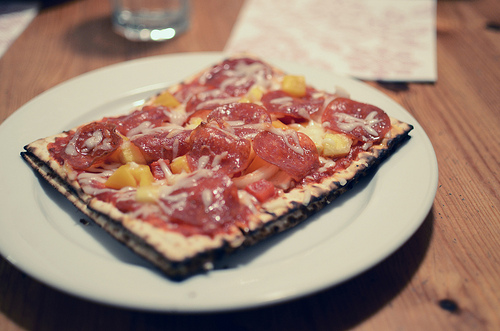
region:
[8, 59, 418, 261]
Flatbread pizza on a white plate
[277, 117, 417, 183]
Burnt edges of flatbread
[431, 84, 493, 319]
Wood table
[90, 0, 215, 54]
Drinking glass on the table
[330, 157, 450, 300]
White plate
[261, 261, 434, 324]
Shadow of the plate on a table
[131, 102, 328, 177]
Many pieces of pepperoni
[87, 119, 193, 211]
Tomato sauce, cheese, and pepperoni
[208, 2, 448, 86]
Paper menu sitting on the table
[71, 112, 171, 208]
Yellow and red pizza toppings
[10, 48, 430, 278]
This is flat bread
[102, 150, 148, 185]
this is yellow cheese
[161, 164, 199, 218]
this is white cheese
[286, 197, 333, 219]
this is burnt bread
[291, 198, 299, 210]
this is the color black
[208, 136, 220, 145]
this is the color red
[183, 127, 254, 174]
this is a pepperoni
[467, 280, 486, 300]
this is the color brown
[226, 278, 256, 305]
this is the color white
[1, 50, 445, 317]
this is a round plate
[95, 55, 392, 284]
pizza on a plate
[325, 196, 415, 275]
white plate above table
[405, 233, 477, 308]
brown table below plate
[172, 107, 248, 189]
red topping on pizza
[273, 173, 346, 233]
brown crust on pizza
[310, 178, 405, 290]
circular plate with food on top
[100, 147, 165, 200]
yellow topping on food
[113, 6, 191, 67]
glass next to plate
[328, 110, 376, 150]
cheese on the topping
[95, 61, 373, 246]
square pizza on table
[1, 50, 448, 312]
pizza on white plate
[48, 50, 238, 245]
pepperoni flatbread pizza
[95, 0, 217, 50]
drinking glass on wooden table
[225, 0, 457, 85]
napkin on wooden table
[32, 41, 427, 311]
white plate with pizza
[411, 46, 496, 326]
unfinished wooden table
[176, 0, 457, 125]
napkin next to white plate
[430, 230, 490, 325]
black spot on wooden table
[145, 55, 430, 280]
crispy pepperoni and fruit pizza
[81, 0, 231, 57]
clear drinking glass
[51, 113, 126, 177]
small slice of pepperoni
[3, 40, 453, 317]
a small white dinner plate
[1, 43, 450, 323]
dinner plate holding pizza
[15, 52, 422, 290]
small square slice of pizza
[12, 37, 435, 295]
small slice of pepperoni pizza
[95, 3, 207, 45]
small empty glass cup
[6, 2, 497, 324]
plate of pizza on table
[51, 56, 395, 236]
delicious bunch of pizza toppings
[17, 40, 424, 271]
cheese and pepperoni pizza on plate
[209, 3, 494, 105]
white napkin on wooden table